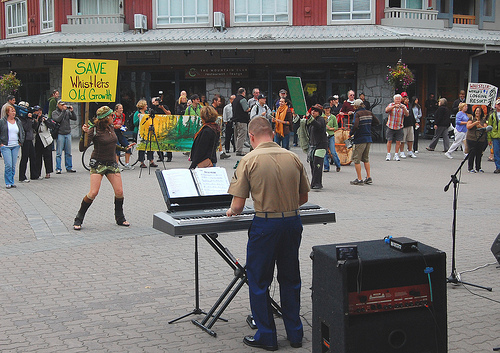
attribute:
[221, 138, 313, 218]
shirt — brown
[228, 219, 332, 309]
pants — blue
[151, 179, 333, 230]
keyboard — black 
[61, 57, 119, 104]
sign — yellow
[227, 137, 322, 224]
shirt — brown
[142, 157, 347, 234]
keyboard — musical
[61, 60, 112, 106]
board — yellow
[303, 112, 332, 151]
shirt — black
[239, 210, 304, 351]
pants — blue